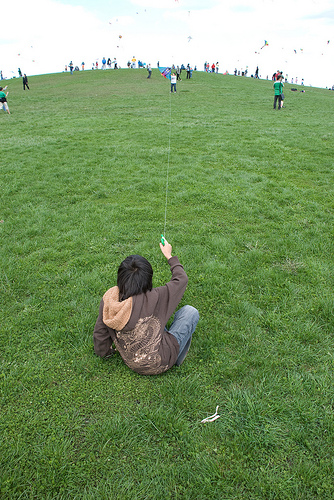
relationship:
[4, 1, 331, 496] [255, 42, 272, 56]
scene shows kite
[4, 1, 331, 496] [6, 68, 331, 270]
scene shows grassy knoll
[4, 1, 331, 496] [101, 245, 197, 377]
scene shows a boy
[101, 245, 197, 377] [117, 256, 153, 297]
boy has hair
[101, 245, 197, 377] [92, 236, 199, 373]
boy has a boy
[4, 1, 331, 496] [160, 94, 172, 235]
scene shows a string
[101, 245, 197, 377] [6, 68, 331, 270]
boy resting upon grassy knoll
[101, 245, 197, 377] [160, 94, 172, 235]
boy holds onto kite string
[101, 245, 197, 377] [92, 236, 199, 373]
boy has boy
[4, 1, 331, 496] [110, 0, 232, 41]
scene shows kites in sky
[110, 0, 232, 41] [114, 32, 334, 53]
sky has flying kites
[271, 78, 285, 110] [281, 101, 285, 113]
person has bag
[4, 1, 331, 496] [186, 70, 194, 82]
scene shows child and person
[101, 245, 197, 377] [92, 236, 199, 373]
boy wearing brown boy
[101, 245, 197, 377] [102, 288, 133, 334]
boy has hood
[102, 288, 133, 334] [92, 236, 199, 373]
hood belongs on boy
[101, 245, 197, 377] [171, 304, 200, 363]
boy has jeans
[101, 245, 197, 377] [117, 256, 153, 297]
boy has black hair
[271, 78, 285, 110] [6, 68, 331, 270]
person standing on grassy knoll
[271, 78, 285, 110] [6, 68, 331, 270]
person stands tall upon grassy knoll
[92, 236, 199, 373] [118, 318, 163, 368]
boy features dragon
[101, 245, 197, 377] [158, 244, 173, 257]
boy has hand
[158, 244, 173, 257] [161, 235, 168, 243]
hand has something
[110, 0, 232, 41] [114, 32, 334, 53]
sky has colorful flying kites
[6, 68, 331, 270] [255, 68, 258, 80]
grassy knoll has person standing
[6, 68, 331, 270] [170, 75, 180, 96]
grassy knoll has standing person in white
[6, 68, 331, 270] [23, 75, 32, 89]
grassy knoll has standing person in black